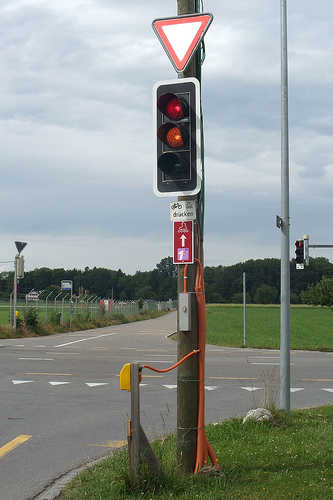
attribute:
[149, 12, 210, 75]
sign — red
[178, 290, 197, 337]
box — electrical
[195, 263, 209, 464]
cord — orange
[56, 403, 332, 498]
grass — green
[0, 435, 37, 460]
line — yellow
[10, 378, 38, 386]
arrow — white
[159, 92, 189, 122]
light — red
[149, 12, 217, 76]
triangle — painted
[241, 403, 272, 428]
rock — white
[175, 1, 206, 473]
post — wooden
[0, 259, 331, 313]
trees — tall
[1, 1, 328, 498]
outside — day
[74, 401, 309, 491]
corner — street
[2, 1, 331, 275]
sky — cloudy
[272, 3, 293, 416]
pole — gray